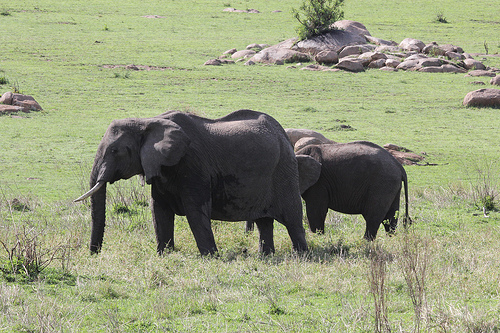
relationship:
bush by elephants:
[0, 214, 71, 286] [76, 103, 425, 267]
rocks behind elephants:
[201, 17, 499, 112] [76, 103, 425, 267]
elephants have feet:
[76, 103, 425, 267] [147, 242, 313, 257]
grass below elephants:
[3, 194, 499, 302] [76, 103, 425, 267]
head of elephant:
[87, 111, 184, 189] [70, 107, 310, 263]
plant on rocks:
[290, 0, 348, 43] [201, 17, 499, 112]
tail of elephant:
[399, 167, 414, 229] [283, 124, 415, 245]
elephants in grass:
[76, 103, 425, 267] [3, 194, 499, 302]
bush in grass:
[0, 214, 71, 286] [3, 194, 499, 302]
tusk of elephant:
[71, 182, 105, 204] [70, 107, 310, 263]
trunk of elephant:
[89, 145, 109, 260] [70, 107, 310, 263]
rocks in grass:
[201, 17, 499, 112] [3, 194, 499, 302]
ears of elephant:
[138, 112, 190, 184] [70, 107, 310, 263]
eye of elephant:
[109, 147, 120, 157] [70, 107, 310, 263]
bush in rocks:
[0, 214, 71, 286] [201, 17, 499, 112]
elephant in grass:
[283, 124, 415, 245] [3, 194, 499, 302]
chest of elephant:
[146, 158, 217, 219] [70, 107, 310, 263]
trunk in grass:
[89, 145, 109, 260] [3, 194, 499, 302]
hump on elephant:
[164, 108, 197, 124] [70, 107, 310, 263]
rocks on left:
[0, 88, 46, 122] [2, 5, 58, 326]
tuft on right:
[466, 178, 497, 216] [446, 0, 498, 327]